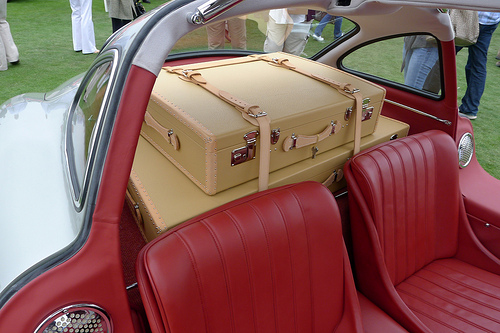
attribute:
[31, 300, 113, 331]
speaker — round, silver, car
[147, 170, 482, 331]
seats — red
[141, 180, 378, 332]
seat — red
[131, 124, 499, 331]
seats — red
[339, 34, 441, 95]
window — glass, triangle shaped, edged in black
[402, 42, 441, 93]
leg — denim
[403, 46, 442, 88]
jeans — blue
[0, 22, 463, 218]
trunk — matching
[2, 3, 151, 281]
car — silver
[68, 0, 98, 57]
pants — white, casual, cotton, bright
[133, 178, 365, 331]
seat — red, car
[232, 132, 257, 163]
latches — metal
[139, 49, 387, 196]
suitcase — tan, leather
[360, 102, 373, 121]
latches — metal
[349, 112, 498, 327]
car seat — red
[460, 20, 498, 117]
pants — blue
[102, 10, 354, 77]
window — large, rear, auto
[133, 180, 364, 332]
car seat — red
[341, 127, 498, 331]
car seat — red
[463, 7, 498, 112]
pants — black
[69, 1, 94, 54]
pants — white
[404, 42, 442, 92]
water — denim, jean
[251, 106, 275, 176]
strap — leather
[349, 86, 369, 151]
strap — leather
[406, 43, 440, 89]
pants — blue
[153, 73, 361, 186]
suitcases — tan